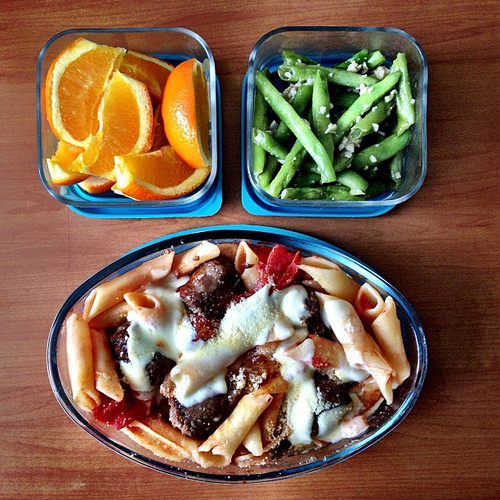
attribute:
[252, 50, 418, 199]
beans —  green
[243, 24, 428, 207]
container —  blue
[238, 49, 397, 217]
lid —  of container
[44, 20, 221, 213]
container —  square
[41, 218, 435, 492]
dish — oval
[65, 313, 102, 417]
tube pasta —  Tube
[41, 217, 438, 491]
bowl —   oval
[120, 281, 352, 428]
white sauce —  White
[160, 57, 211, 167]
wedge —  orange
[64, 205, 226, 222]
lid —  blue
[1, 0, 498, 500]
wood — table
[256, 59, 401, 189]
beans — within square container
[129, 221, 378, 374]
cheese —  mozzarella ,  melted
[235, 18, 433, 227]
dish — rectangular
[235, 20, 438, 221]
container — clear